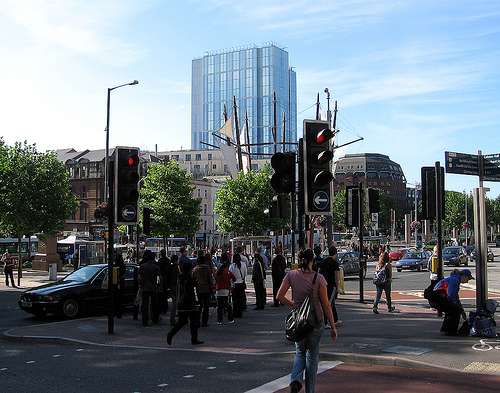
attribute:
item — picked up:
[471, 296, 493, 351]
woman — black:
[274, 240, 337, 391]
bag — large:
[277, 261, 324, 343]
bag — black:
[282, 292, 329, 339]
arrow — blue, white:
[208, 104, 260, 193]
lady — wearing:
[424, 261, 480, 318]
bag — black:
[283, 270, 323, 345]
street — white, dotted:
[15, 244, 498, 386]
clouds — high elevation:
[25, 25, 99, 123]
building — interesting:
[333, 150, 407, 235]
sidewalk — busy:
[4, 285, 498, 390]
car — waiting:
[469, 242, 495, 264]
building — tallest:
[186, 39, 298, 163]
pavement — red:
[356, 259, 496, 306]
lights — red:
[112, 123, 467, 258]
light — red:
[301, 116, 336, 217]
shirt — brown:
[283, 262, 330, 315]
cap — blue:
[463, 268, 479, 285]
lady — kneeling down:
[422, 258, 482, 332]